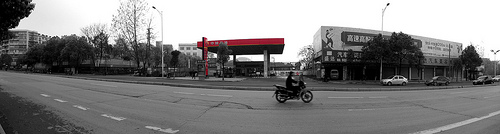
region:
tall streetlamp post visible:
[379, 0, 392, 90]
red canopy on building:
[191, 24, 278, 76]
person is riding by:
[269, 66, 306, 96]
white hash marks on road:
[0, 80, 167, 132]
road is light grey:
[37, 74, 238, 129]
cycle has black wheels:
[270, 86, 317, 109]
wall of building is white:
[310, 30, 454, 60]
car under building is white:
[380, 70, 407, 90]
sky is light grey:
[307, 1, 379, 31]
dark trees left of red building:
[22, 27, 125, 62]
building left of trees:
[0, 23, 47, 58]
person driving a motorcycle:
[271, 70, 318, 112]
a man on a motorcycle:
[272, 69, 310, 104]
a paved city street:
[6, 65, 497, 131]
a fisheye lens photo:
[3, 3, 496, 130]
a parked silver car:
[382, 76, 410, 86]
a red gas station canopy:
[188, 31, 283, 78]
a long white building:
[303, 29, 465, 83]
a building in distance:
[0, 30, 42, 62]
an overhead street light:
[148, 0, 168, 77]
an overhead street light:
[375, 0, 388, 80]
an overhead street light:
[485, 45, 498, 77]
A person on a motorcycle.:
[267, 68, 312, 106]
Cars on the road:
[376, 67, 498, 93]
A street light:
[148, 2, 170, 77]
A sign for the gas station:
[201, 38, 209, 75]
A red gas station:
[197, 37, 281, 82]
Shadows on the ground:
[0, 81, 55, 132]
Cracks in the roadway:
[153, 93, 243, 117]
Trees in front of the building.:
[360, 35, 433, 66]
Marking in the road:
[44, 88, 148, 132]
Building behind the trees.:
[0, 26, 58, 61]